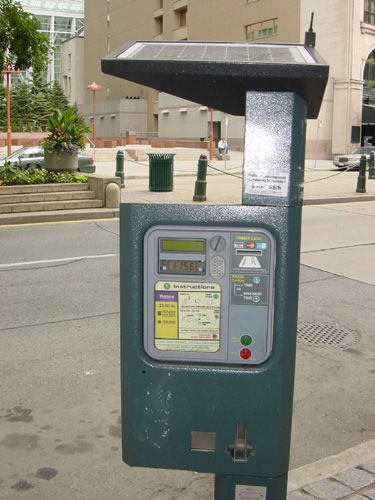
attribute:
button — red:
[240, 348, 251, 361]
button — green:
[242, 335, 252, 347]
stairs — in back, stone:
[3, 184, 106, 224]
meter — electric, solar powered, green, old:
[97, 40, 333, 500]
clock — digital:
[166, 259, 198, 277]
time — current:
[164, 261, 198, 272]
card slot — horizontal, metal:
[236, 249, 261, 258]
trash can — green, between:
[146, 153, 176, 195]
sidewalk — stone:
[120, 171, 374, 204]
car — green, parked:
[3, 144, 100, 176]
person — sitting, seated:
[217, 137, 229, 155]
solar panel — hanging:
[115, 46, 312, 61]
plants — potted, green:
[45, 113, 82, 153]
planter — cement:
[44, 146, 80, 172]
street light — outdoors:
[89, 82, 101, 148]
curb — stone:
[5, 211, 119, 220]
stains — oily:
[345, 349, 373, 378]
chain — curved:
[209, 164, 360, 182]